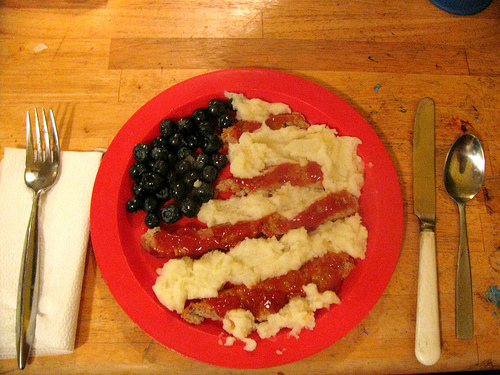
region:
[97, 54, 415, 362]
plate filled with food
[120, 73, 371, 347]
food on top of plate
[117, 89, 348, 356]
food in shape of american flag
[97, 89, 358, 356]
american flag made of food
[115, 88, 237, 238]
blue berries on red plate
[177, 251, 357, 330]
slice of bacon on plate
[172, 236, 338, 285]
mashed potatoes on plate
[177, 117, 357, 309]
stripes from food on plate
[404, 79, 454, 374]
silver knife on wooden table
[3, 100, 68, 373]
metal fork on napkin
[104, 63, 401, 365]
a plate of food is on the table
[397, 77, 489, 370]
a soon and knife are on the right hand side of the plate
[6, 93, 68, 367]
a fork is to the left of the plate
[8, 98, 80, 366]
the fork rests on a napkin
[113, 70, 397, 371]
the plate the food is on is red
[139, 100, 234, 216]
blueberries are on the plate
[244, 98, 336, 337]
mashed potatoes are on the plate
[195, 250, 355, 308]
breaded chicken strips are on the plate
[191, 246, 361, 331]
the chicken is covered in ketchup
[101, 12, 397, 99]
the surface the plate is on appears to be made up wood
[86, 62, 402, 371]
Red plate is on the table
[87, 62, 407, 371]
Round plate is on the table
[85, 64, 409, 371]
Round red plate is on the table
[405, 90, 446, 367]
Knife is on the table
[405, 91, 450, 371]
Butter knife is on the table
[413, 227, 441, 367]
Knife has a white handle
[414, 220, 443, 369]
Butter knife has a white handle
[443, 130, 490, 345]
Spoon is on the table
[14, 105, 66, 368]
Fork is on a napkin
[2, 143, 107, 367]
Napkin is on the table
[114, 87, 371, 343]
an American flag out of food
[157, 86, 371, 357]
the white is mashed potatoes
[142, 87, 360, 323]
the red is ketchup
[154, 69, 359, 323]
meat under the ketchup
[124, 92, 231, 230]
the blue is blueberries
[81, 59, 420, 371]
the plate is red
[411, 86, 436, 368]
a knife beside the plate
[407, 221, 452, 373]
the handle is white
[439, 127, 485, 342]
a spoon next to the knife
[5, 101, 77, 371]
a fork beside the plate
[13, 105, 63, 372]
Fork sitting on white napkin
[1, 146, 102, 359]
White napkin with fork sitting on it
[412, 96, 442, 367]
Knife to the left of a spoon on a wooden table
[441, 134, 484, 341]
Spoon set on a table next to a knife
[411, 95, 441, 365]
Knife in between spoon and plate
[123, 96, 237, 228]
Blueberries on a red plate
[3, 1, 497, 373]
Wooden table with a dinner setting on it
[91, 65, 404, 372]
Red plate to the right of a fork and napkin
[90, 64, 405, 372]
Red plate to the left of a knife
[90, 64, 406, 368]
Red plate on a wooden table with silverware settin